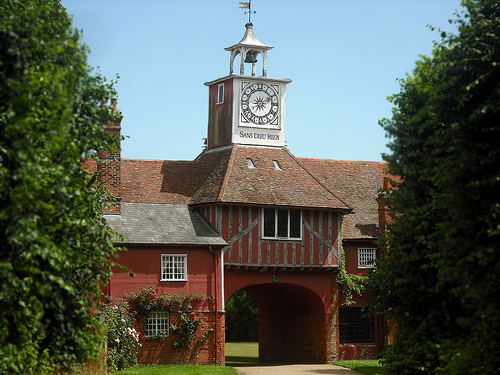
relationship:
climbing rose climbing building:
[106, 285, 216, 365] [77, 5, 402, 373]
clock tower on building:
[203, 1, 290, 145] [80, 156, 387, 362]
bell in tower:
[234, 42, 275, 69] [103, 15, 412, 281]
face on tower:
[244, 91, 277, 124] [81, 22, 394, 372]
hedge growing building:
[354, 0, 500, 375] [77, 5, 402, 373]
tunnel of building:
[224, 270, 317, 355] [56, 60, 365, 372]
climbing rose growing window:
[106, 285, 216, 365] [142, 303, 178, 340]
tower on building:
[184, 21, 338, 254] [77, 5, 402, 373]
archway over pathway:
[219, 266, 343, 371] [226, 350, 347, 374]